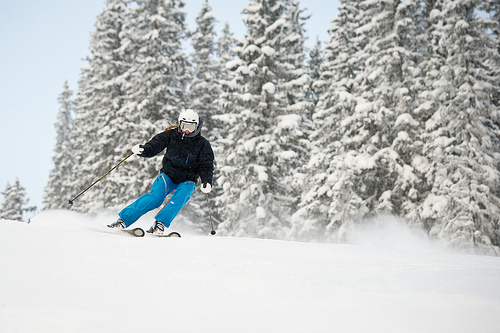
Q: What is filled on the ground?
A: White snow.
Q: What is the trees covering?
A: White snow.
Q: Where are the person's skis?
A: On the snow.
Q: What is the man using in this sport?
A: Black ski poles.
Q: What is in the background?
A: Pine trees.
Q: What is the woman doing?
A: Skatting.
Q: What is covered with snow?
A: Tree.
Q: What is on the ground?
A: Snow.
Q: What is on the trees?
A: Snow.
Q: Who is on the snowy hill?
A: A woman.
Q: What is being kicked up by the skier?
A: Puff of snow.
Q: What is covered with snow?
A: Many trees.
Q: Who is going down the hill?
A: The woman.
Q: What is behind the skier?
A: Trees.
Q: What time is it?
A: Afternoon.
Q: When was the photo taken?
A: During the daytime.